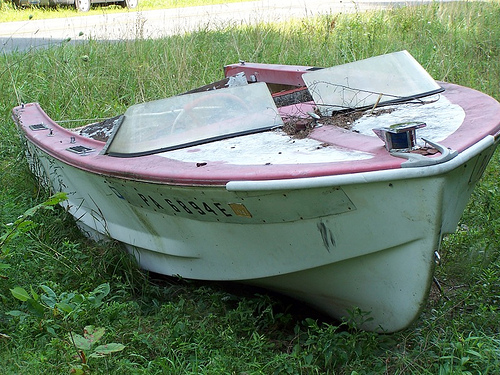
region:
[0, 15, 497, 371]
The vegetation is tall.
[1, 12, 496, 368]
The vegetation is green.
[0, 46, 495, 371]
The vegetation is overgrown.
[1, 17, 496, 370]
The vegetation is living.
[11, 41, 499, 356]
The boat is old.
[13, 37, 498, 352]
The boat is in grass.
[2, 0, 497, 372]
The boat is faded.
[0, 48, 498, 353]
The boat is red and white.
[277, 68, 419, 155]
Weeds and dirt are on top of the boat.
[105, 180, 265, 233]
Letters and numbers on side of boat.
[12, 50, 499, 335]
A white and red boat.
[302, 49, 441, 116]
A right side windshield on a boat.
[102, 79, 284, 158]
Left side window on a boat.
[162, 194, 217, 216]
Number 6894 on a boat.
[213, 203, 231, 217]
Letter E on a boat.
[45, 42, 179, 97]
Tall weeds and grass behind a boat.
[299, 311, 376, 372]
Green grass sticking up in front of a boat.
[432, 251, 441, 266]
Metal loop on the front of a boat.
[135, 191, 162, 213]
Letters PA on the front of a boat.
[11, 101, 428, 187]
Red trim on the edge of a boat.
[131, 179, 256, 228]
Sign on the side of the boat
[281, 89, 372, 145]
Sticks on top of the boat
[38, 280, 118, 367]
Small plant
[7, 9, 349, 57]
Gray pavement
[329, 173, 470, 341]
Front of the boat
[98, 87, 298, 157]
Glass on front of the boat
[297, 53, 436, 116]
Glass on front of the boat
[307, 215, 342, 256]
Black mark on the boat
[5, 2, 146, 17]
Bottom of car in the background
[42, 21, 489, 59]
Tall grass behind boat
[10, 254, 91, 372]
The plants are tall.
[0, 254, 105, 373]
The plants are green.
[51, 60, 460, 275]
The boat is dirty.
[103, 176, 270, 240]
A number is on the boat.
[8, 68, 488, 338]
The boat is white and red.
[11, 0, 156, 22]
A car is in the background.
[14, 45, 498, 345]
The boat is not in use.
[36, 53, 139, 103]
The grass is two.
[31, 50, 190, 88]
The grass is tall.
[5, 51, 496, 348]
The boat is on the ground.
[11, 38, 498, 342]
A ship in the yard.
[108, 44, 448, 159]
Windsheld on the boat.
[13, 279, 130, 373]
weeds in the yard.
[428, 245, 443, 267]
A hook on the boat.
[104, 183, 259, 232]
Markings on the boat.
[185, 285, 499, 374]
The boat in the grass.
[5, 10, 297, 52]
The road.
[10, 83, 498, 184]
the boats pink trim.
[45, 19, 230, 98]
The tall wild grass.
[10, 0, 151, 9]
A car in the yard.